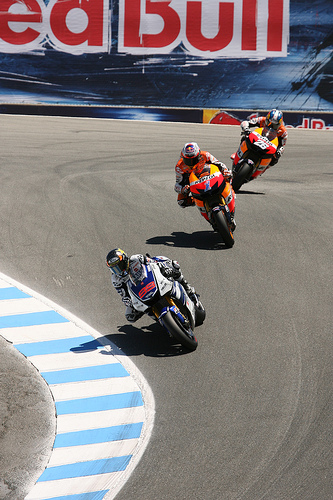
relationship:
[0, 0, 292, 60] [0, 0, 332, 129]
slogan on sign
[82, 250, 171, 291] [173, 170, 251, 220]
person on motorcycle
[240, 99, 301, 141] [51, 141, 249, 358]
person on motorcyclke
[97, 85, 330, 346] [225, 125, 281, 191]
people racing motorbikes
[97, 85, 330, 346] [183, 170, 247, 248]
people racing motorbikes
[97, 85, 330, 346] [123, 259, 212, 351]
people racing motorbikes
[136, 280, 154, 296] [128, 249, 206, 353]
number on bike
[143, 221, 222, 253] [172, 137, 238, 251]
shadow of rider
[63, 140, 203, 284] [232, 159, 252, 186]
marks left by tire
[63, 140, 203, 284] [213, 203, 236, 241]
marks left by tire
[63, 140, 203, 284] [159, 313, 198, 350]
marks left by tire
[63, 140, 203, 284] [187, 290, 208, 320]
marks left by tire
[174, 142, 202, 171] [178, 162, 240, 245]
man tilting bike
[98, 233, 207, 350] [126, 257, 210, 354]
person riding bike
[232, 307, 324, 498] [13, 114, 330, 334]
tracks on road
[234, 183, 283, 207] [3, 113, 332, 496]
shadow on ground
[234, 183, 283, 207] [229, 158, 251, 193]
shadow of tire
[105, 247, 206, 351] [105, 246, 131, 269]
person wearing helmet